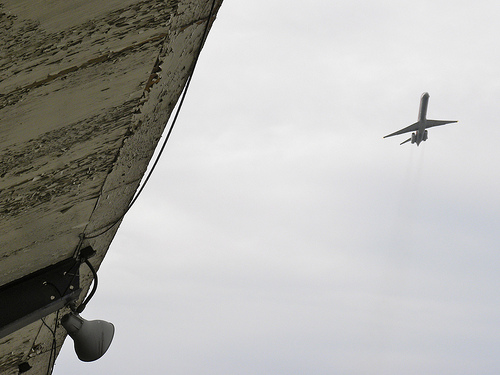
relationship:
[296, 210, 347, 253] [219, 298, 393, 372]
clouds against sky